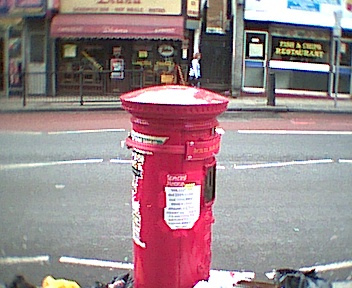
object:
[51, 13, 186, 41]
awning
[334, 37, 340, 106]
pole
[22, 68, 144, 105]
fencing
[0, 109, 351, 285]
street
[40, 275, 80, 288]
garbage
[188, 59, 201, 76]
jacket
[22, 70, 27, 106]
rack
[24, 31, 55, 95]
door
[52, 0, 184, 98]
storefront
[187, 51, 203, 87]
woman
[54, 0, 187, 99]
building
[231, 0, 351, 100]
building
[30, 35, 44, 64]
window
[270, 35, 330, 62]
window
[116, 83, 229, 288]
hydrant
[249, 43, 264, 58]
sign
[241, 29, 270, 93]
door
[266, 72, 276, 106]
post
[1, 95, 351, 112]
sidewalk